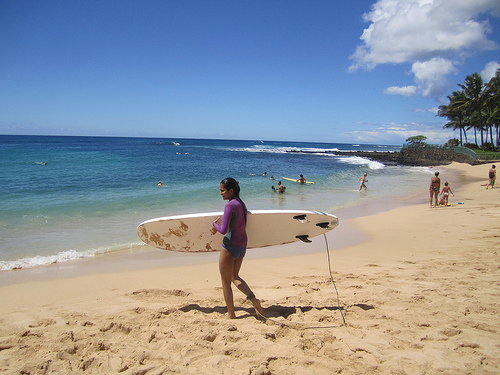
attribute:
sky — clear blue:
[3, 3, 497, 147]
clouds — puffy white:
[346, 6, 499, 142]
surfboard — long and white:
[132, 190, 350, 275]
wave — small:
[5, 249, 97, 271]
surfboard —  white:
[128, 207, 343, 257]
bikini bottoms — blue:
[221, 238, 256, 263]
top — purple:
[226, 193, 239, 247]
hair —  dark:
[219, 146, 266, 259]